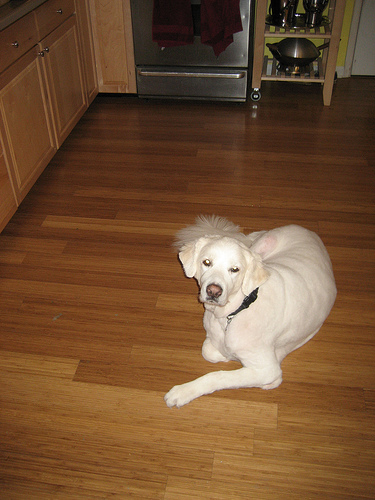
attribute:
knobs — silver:
[4, 0, 70, 56]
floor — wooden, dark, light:
[4, 88, 373, 498]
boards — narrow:
[97, 113, 303, 201]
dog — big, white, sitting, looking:
[156, 201, 346, 419]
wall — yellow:
[256, 0, 363, 96]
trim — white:
[343, 0, 368, 90]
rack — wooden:
[255, 0, 345, 110]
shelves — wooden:
[263, 12, 331, 101]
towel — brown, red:
[152, 2, 249, 57]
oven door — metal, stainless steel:
[127, 0, 256, 117]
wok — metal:
[270, 40, 321, 70]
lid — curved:
[280, 38, 322, 59]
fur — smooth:
[274, 245, 324, 309]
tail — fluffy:
[173, 207, 275, 258]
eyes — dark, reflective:
[197, 254, 244, 285]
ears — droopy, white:
[165, 234, 269, 294]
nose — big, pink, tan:
[198, 279, 230, 308]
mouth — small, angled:
[197, 293, 224, 310]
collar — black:
[215, 275, 273, 317]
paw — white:
[156, 377, 210, 415]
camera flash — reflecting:
[197, 257, 241, 284]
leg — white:
[244, 226, 297, 267]